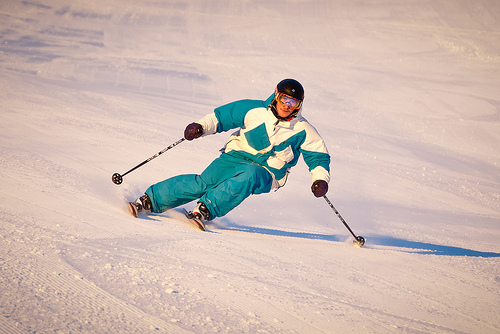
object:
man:
[129, 78, 332, 234]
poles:
[110, 136, 187, 184]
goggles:
[276, 90, 300, 110]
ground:
[0, 0, 500, 332]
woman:
[127, 77, 332, 232]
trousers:
[142, 152, 272, 227]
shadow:
[210, 214, 500, 258]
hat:
[270, 78, 304, 122]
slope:
[85, 58, 488, 333]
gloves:
[183, 122, 203, 142]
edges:
[0, 0, 10, 333]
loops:
[180, 13, 484, 63]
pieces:
[370, 40, 434, 104]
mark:
[125, 55, 209, 81]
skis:
[181, 202, 206, 230]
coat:
[197, 92, 332, 194]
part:
[278, 87, 285, 95]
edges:
[240, 189, 248, 198]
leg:
[197, 162, 277, 218]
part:
[391, 238, 397, 243]